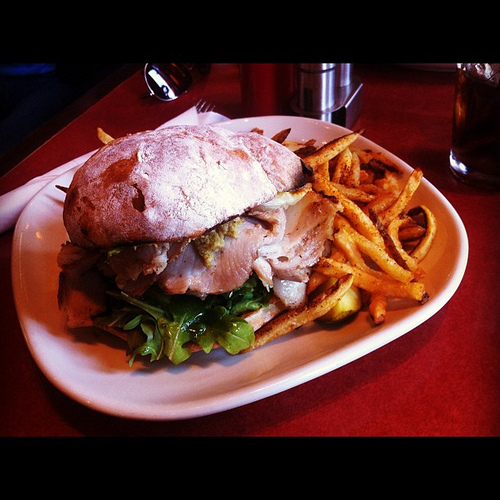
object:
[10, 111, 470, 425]
plate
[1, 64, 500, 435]
table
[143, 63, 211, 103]
glasses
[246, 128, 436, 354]
french fries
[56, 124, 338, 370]
sandwich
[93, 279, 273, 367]
lettuce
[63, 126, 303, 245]
roll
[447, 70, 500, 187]
coke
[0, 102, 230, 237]
silverware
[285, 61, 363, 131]
salt and pepper shak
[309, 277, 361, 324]
pickle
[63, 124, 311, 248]
bread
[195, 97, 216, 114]
fork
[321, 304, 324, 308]
speck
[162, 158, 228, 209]
powder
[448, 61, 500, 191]
glass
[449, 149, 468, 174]
light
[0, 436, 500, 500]
shadow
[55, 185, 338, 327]
pork